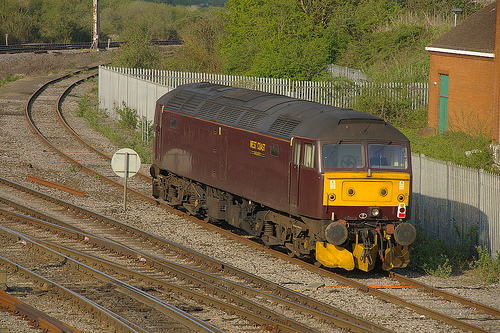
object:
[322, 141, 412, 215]
train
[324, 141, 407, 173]
windows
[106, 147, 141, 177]
sign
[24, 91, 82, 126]
railroadtracks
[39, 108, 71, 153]
gravel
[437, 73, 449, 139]
door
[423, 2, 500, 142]
building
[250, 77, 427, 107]
fence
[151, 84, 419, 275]
train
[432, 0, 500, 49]
roof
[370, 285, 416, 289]
stripe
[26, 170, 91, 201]
pole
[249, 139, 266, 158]
wrting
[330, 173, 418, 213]
trainengine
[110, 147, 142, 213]
back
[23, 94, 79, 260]
train tracks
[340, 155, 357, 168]
steeringwheel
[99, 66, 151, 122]
picket fence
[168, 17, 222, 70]
shrubs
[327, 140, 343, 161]
windshieldwipers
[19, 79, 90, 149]
traintrack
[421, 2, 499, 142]
structure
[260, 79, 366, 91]
white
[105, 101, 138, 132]
weeds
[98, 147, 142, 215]
post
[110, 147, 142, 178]
round sign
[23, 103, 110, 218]
traintracks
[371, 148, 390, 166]
driver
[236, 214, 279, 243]
wheels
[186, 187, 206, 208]
gears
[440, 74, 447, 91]
window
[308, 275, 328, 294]
wood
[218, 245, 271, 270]
ground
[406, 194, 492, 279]
shadow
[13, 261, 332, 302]
traintracks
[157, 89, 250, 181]
traincar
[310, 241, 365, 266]
trim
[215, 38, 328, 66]
bushes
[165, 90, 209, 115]
ehaustvent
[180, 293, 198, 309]
railroard ties